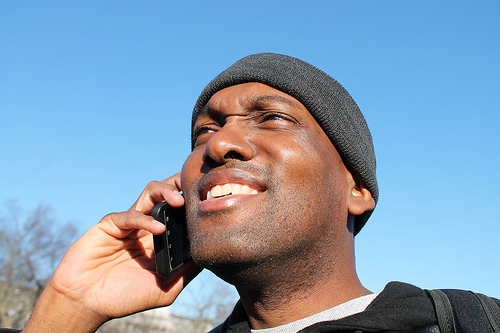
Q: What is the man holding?
A: Cell phone.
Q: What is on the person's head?
A: Stocking cap.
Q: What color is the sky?
A: Blue.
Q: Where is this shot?
A: On the ground.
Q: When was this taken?
A: Daytime.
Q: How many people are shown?
A: 1.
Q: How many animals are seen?
A: 0.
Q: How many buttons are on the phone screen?
A: 4.